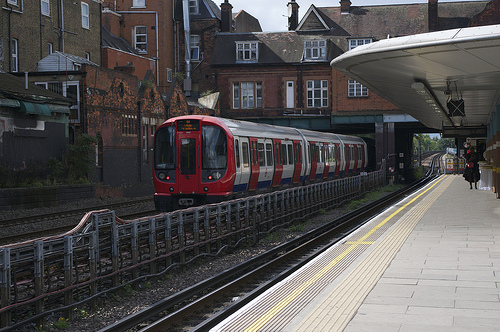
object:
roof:
[326, 39, 478, 141]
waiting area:
[328, 24, 500, 199]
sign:
[446, 96, 466, 117]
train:
[148, 114, 371, 196]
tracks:
[18, 160, 428, 330]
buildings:
[3, 1, 485, 186]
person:
[465, 149, 481, 190]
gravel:
[125, 262, 180, 297]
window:
[233, 81, 263, 109]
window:
[304, 40, 327, 60]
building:
[210, 2, 479, 125]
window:
[306, 80, 328, 109]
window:
[235, 41, 258, 61]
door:
[235, 136, 250, 186]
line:
[243, 172, 446, 329]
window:
[188, 35, 201, 62]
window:
[187, 0, 198, 14]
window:
[128, 0, 146, 9]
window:
[134, 25, 147, 52]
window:
[66, 85, 79, 120]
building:
[176, 1, 216, 104]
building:
[108, 0, 175, 89]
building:
[29, 69, 84, 133]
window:
[258, 143, 265, 167]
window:
[287, 144, 293, 165]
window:
[200, 125, 228, 183]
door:
[285, 81, 295, 109]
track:
[135, 169, 439, 330]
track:
[0, 195, 155, 240]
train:
[151, 101, 370, 218]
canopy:
[20, 100, 53, 117]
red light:
[163, 172, 171, 181]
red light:
[207, 175, 212, 180]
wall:
[217, 65, 408, 119]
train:
[118, 100, 392, 189]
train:
[141, 103, 393, 208]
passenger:
[460, 144, 480, 189]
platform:
[209, 170, 499, 330]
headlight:
[206, 172, 214, 182]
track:
[170, 247, 306, 316]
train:
[147, 109, 377, 214]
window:
[235, 139, 241, 169]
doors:
[235, 134, 370, 177]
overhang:
[327, 34, 485, 82]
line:
[321, 200, 384, 286]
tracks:
[217, 219, 319, 259]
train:
[229, 121, 354, 171]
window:
[286, 80, 295, 108]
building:
[217, 21, 346, 137]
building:
[211, 22, 341, 118]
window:
[242, 142, 249, 168]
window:
[258, 142, 274, 166]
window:
[235, 139, 250, 168]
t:
[446, 97, 464, 121]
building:
[206, 5, 497, 140]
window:
[34, 82, 47, 90]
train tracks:
[0, 151, 443, 329]